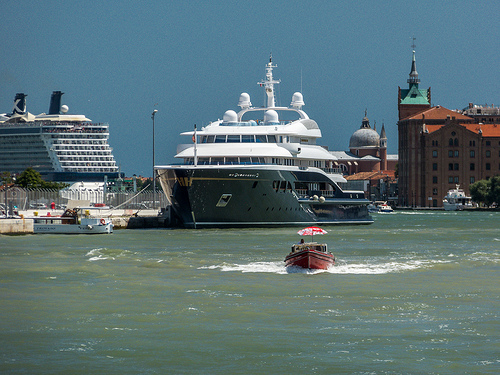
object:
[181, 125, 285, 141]
bridge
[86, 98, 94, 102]
clouds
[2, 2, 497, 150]
sky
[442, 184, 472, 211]
boat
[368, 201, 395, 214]
boat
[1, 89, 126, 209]
cruise ship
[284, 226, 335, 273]
boat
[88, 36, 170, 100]
white clouds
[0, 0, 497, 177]
blue sky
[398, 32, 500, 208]
building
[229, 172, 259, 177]
writing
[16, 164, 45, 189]
trees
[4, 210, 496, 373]
water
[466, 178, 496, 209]
green tree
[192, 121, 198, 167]
flag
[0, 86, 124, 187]
ship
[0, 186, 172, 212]
metal fence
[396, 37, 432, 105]
roof top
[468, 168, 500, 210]
trees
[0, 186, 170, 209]
fence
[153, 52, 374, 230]
boat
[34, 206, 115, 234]
boat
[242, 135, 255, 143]
window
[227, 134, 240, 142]
window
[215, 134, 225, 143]
window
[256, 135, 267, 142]
window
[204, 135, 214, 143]
window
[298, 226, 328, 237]
umbrella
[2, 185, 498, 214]
shoreline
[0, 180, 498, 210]
shore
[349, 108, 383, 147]
dome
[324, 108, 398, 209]
building